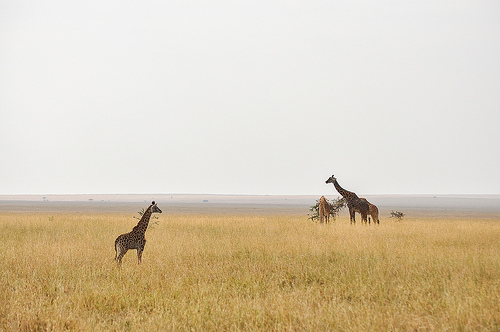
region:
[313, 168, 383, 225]
giraffes by a small tree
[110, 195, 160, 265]
baby giraffe by small bush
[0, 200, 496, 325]
flat grassland landscape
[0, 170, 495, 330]
giraffes on flat grasslands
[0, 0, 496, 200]
gray skies in the background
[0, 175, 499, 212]
a flat horizon in the distance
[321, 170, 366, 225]
a large giraffe in the grassland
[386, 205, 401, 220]
a small isolated bush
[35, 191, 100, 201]
isolated trees in the distance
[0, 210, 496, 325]
dry grasslands with some green foliage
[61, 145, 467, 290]
Giraffes in an open space.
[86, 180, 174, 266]
A little giraffe.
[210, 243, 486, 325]
The grass is brownish.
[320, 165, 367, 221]
The giraffe is standing up.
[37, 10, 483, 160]
The sky is a light gray color.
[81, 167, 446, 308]
Several giraffes are standing in a brown grass area.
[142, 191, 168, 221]
A giraffe head.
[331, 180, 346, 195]
A giraffe neck.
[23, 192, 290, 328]
The ground is flat where the giraffe is standing.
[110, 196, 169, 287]
The giraffe has brown spots.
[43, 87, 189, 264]
a tall giraffe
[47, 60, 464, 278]
two tall giraffes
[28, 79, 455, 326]
giraffes in tall grass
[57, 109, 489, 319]
giraffes during the day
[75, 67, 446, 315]
giraffes in the wild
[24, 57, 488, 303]
two giraffes standing up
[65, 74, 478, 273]
two tall giraffes in the grass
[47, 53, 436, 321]
two tall giraffes during the day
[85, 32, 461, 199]
clear blue skies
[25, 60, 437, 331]
two giraffes in the field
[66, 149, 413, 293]
giraffes standing in a field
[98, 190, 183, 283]
giraffe looking toward right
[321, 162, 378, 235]
giraffe looking toward right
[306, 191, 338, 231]
giraffe looking toward back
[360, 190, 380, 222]
giraffe covered by taller one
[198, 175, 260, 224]
horizon in the background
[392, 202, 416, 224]
small tree shorter than giraffe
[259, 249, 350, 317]
patch of light colored grass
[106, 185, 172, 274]
giraffe with tan spots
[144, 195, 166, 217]
head of giraffe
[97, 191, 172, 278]
giraffe in field of grass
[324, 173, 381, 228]
tall giraffe looking away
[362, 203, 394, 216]
giraffe behind tall giraffe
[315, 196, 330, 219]
giraffe is facing tree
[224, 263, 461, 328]
grass is brown and tall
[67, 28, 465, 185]
skies are a murky grey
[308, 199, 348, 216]
tree behind giraffe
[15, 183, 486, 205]
plain in the distance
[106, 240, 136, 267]
tale of giraffe